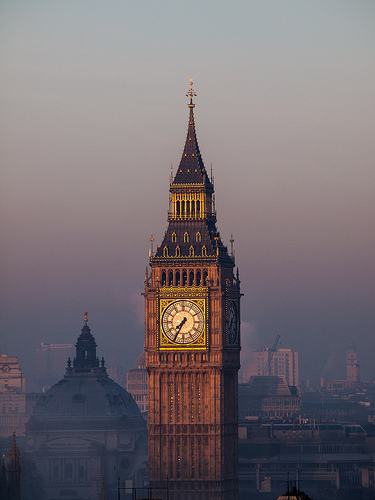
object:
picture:
[0, 1, 373, 497]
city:
[0, 334, 375, 500]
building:
[346, 340, 359, 381]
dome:
[346, 341, 356, 354]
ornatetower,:
[141, 78, 245, 498]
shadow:
[223, 370, 239, 425]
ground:
[236, 478, 252, 500]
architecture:
[141, 78, 245, 499]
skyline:
[1, 76, 373, 499]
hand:
[176, 319, 185, 329]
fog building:
[346, 339, 360, 381]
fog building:
[242, 348, 298, 387]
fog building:
[0, 354, 25, 393]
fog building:
[126, 351, 148, 414]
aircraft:
[156, 296, 209, 350]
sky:
[0, 0, 375, 63]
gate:
[118, 477, 202, 500]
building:
[23, 311, 150, 499]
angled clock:
[226, 299, 239, 345]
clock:
[161, 299, 204, 344]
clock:
[1, 364, 10, 373]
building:
[0, 354, 25, 437]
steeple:
[167, 78, 216, 221]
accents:
[172, 190, 205, 218]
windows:
[160, 268, 166, 286]